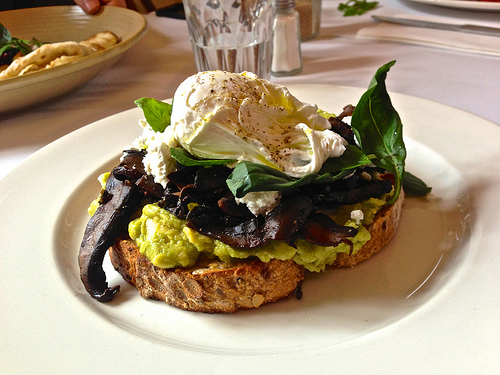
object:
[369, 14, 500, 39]
silverware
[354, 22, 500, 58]
white napkin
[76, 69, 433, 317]
sandwhich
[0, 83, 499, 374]
plate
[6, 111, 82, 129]
table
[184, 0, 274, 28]
glass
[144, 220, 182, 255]
guacamole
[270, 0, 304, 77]
salt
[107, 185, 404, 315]
bread